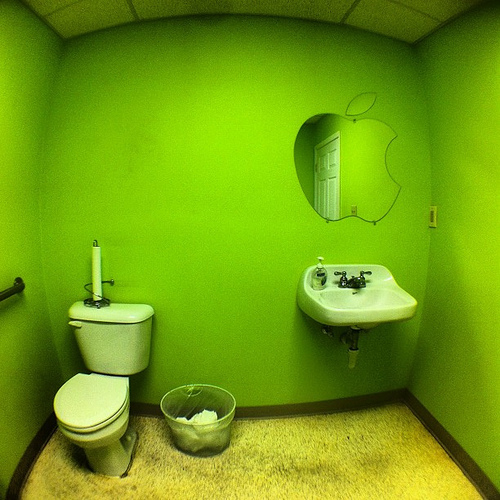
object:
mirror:
[281, 81, 407, 234]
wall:
[33, 20, 435, 412]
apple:
[293, 86, 401, 224]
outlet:
[429, 203, 439, 227]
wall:
[408, 8, 500, 500]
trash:
[167, 398, 227, 450]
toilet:
[53, 300, 151, 476]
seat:
[48, 367, 131, 444]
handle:
[69, 320, 83, 328]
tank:
[64, 293, 151, 373]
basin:
[297, 261, 418, 368]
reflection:
[304, 131, 343, 221]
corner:
[3, 230, 192, 499]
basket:
[157, 381, 238, 455]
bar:
[0, 276, 26, 303]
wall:
[0, 4, 78, 500]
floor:
[14, 380, 500, 497]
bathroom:
[1, 4, 499, 483]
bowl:
[53, 369, 142, 480]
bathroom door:
[312, 132, 352, 216]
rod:
[0, 278, 28, 301]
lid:
[67, 301, 153, 324]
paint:
[33, 10, 424, 408]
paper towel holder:
[83, 239, 116, 308]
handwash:
[311, 256, 328, 290]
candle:
[92, 241, 102, 298]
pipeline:
[0, 268, 31, 306]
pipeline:
[322, 319, 360, 370]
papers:
[166, 402, 228, 453]